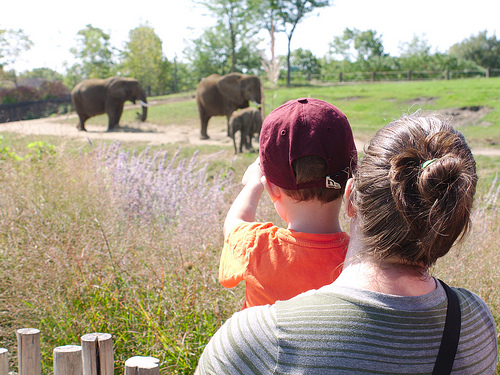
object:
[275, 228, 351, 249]
collar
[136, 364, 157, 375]
part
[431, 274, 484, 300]
shoulder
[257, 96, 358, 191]
hat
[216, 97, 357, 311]
boy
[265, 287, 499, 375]
back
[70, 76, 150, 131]
elephant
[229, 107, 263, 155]
elephant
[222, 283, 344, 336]
woman's shoulder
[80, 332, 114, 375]
fence post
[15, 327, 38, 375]
fence post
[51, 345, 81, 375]
fence post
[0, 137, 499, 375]
grass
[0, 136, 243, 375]
bush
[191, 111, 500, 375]
woman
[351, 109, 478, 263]
hair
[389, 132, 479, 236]
bun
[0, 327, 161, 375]
fence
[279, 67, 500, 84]
wooden fence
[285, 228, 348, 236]
edge of a collar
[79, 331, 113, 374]
part of a pole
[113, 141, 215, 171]
part of a ground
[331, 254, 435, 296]
part of a neck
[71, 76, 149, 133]
elephant feeding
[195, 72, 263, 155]
elephant and calf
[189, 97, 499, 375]
boy and his mother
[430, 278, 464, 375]
bag strap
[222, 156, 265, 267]
boy is pointing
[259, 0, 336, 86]
all green trees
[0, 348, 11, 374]
small wooden poles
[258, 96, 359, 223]
boy's head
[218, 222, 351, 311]
an orange shirt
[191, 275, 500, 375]
striped shirt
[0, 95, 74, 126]
wooden fence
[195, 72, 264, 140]
an adult elephant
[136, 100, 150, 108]
white tusk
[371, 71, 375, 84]
wooden post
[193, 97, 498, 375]
two people looking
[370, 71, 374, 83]
wooden fence posts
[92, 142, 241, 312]
tall dry grass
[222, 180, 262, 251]
left hand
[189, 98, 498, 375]
holding a child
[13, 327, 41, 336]
top of a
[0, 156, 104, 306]
tall weeds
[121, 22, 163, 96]
row of trees